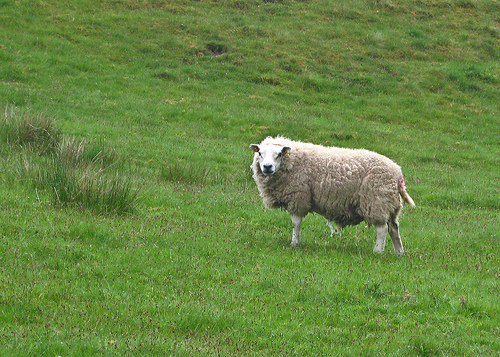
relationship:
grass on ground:
[1, 0, 498, 352] [1, 1, 484, 354]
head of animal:
[247, 142, 292, 177] [249, 133, 416, 255]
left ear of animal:
[279, 146, 291, 158] [249, 133, 416, 255]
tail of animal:
[398, 165, 417, 207] [249, 133, 416, 255]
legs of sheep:
[370, 210, 400, 256] [196, 111, 443, 290]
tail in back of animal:
[398, 171, 416, 209] [249, 133, 416, 255]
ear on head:
[252, 132, 410, 270] [250, 140, 290, 184]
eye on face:
[271, 153, 286, 162] [248, 138, 285, 178]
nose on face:
[261, 161, 275, 177] [260, 147, 275, 180]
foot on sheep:
[373, 245, 385, 254] [229, 112, 431, 267]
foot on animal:
[370, 238, 389, 255] [249, 133, 416, 255]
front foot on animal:
[286, 231, 303, 247] [249, 133, 416, 255]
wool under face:
[250, 135, 416, 228] [258, 150, 283, 174]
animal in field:
[249, 133, 416, 255] [6, 5, 492, 350]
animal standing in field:
[249, 133, 416, 255] [6, 5, 492, 350]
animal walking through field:
[249, 133, 416, 255] [74, 96, 495, 352]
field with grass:
[6, 5, 492, 350] [398, 79, 480, 116]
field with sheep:
[6, 5, 492, 350] [256, 140, 418, 248]